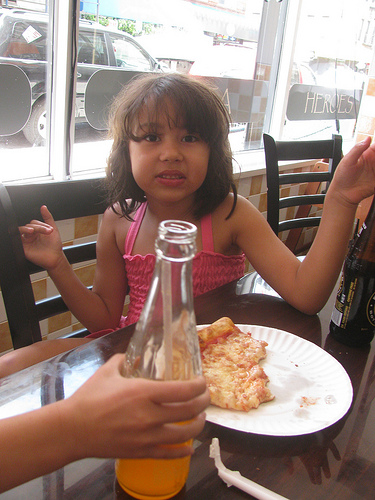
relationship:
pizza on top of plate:
[207, 327, 259, 411] [278, 346, 335, 438]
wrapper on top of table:
[213, 451, 255, 483] [264, 449, 347, 473]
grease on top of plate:
[280, 372, 320, 414] [278, 346, 335, 438]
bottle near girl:
[140, 219, 192, 493] [71, 72, 281, 300]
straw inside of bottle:
[151, 258, 181, 370] [140, 219, 192, 493]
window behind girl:
[274, 1, 359, 126] [71, 72, 281, 300]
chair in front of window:
[258, 134, 313, 246] [274, 1, 359, 126]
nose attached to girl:
[160, 151, 184, 163] [71, 72, 281, 300]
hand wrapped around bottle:
[79, 357, 200, 460] [112, 218, 205, 499]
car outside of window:
[7, 18, 110, 119] [274, 1, 359, 126]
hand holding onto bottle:
[79, 357, 200, 460] [140, 219, 192, 493]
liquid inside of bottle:
[127, 468, 182, 490] [140, 219, 192, 493]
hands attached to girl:
[5, 204, 64, 268] [71, 72, 281, 300]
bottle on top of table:
[140, 219, 192, 493] [264, 449, 347, 473]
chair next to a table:
[258, 134, 313, 246] [235, 286, 271, 311]